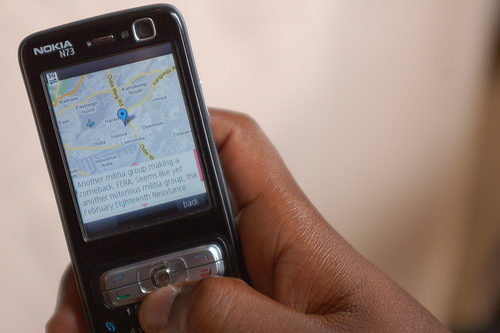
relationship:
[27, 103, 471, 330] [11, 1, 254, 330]
person holding phone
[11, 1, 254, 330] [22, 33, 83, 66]
phone made by nokia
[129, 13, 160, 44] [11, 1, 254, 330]
camera on phone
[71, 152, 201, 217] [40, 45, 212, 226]
writing on phone screen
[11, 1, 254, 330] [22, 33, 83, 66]
phone seen brand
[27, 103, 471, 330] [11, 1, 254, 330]
hand holding phone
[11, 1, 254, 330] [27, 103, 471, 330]
cellphone on hand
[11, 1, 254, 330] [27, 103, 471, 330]
cellphone in person hand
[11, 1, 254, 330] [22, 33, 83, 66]
cellphone brand nokia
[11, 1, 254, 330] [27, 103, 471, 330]
phone in hand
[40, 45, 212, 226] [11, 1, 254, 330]
map on cellphone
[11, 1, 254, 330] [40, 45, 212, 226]
cellphone with street map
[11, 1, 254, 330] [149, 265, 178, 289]
cellphone with silver button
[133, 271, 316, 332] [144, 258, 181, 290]
finger pressing cell button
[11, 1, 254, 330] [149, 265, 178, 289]
cellphone has silver button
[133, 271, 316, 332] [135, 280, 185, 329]
thumb has nail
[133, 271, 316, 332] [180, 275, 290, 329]
thumb has wrinkles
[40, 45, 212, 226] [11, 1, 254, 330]
map on phone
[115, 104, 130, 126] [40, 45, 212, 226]
point on map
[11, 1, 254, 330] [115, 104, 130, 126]
phone has a maker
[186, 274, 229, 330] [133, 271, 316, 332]
knuckle on finger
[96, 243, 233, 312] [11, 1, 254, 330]
buttons on phone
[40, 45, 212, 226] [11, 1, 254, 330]
face of phone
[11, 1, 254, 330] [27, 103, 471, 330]
cell phone in hand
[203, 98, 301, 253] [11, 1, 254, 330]
finger behind cell phone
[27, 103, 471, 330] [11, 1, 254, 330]
hand holding cell phone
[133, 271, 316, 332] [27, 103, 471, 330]
thumb of hand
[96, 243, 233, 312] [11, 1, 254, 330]
buttons on cellphone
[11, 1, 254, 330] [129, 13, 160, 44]
cell phone has camera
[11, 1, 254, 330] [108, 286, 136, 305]
cell phone has green button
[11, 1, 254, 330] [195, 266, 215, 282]
cellphone has red button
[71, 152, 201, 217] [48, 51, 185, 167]
text under map